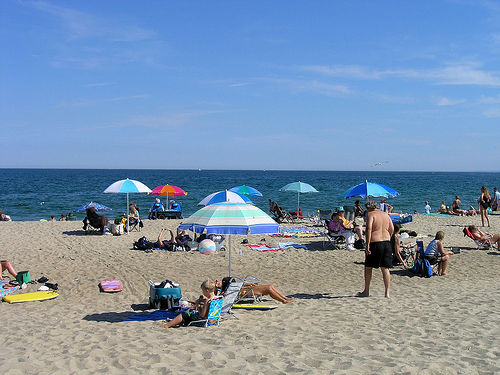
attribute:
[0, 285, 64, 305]
board — BOOGIE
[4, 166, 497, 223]
water — blue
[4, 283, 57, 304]
boogie board — yellow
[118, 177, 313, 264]
umbrella — pink 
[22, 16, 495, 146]
sky — clear blue 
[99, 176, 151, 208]
umbrella — blue, white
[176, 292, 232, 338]
chair — small